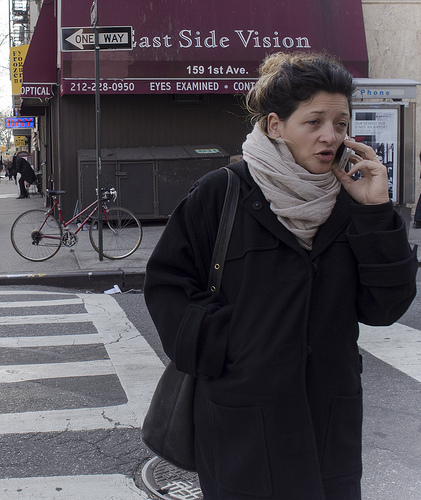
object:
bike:
[9, 183, 143, 262]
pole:
[93, 21, 104, 263]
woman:
[141, 47, 420, 499]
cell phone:
[333, 142, 352, 172]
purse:
[141, 164, 241, 474]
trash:
[101, 284, 124, 296]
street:
[0, 279, 421, 499]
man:
[7, 156, 37, 200]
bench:
[22, 169, 43, 199]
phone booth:
[348, 77, 418, 241]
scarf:
[241, 121, 353, 252]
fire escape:
[7, 0, 32, 52]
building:
[4, 0, 421, 229]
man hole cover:
[140, 451, 205, 499]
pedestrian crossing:
[1, 284, 177, 499]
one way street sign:
[60, 24, 134, 53]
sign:
[3, 115, 36, 131]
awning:
[55, 0, 368, 98]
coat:
[141, 152, 418, 500]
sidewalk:
[0, 168, 168, 293]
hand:
[330, 138, 392, 207]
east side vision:
[130, 26, 311, 52]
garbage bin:
[77, 143, 231, 223]